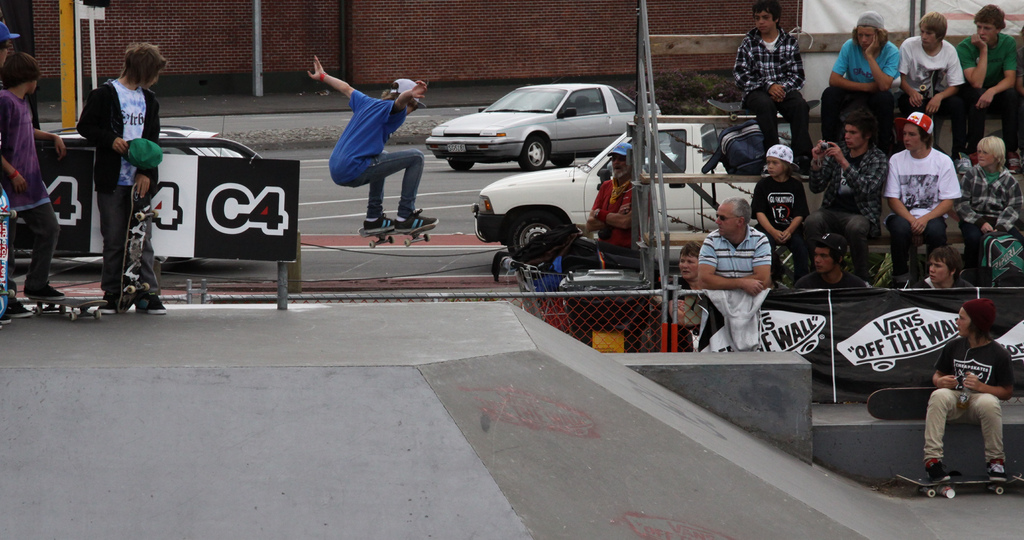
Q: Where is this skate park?
A: On the street.